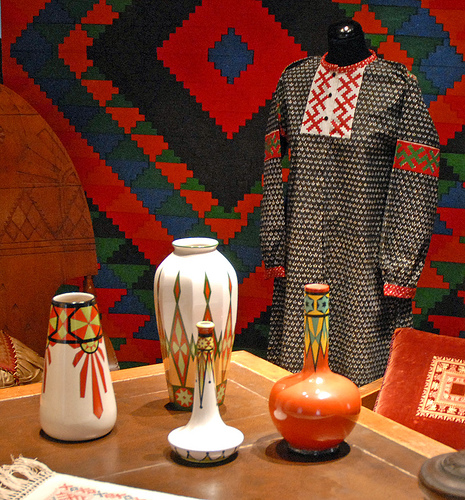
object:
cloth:
[0, 450, 200, 500]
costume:
[260, 49, 439, 387]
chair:
[0, 85, 122, 391]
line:
[33, 279, 365, 467]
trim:
[195, 102, 221, 129]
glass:
[267, 282, 361, 452]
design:
[300, 52, 376, 136]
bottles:
[263, 281, 362, 458]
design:
[0, 0, 465, 368]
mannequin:
[260, 21, 442, 389]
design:
[389, 137, 439, 177]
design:
[302, 290, 331, 369]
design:
[413, 354, 463, 420]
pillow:
[372, 325, 465, 452]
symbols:
[321, 49, 378, 72]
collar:
[319, 47, 377, 75]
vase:
[36, 288, 119, 445]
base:
[287, 438, 341, 454]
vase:
[154, 234, 240, 409]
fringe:
[0, 449, 52, 498]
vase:
[168, 317, 246, 468]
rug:
[0, 327, 49, 390]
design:
[0, 341, 7, 364]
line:
[305, 116, 324, 133]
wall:
[0, 0, 464, 369]